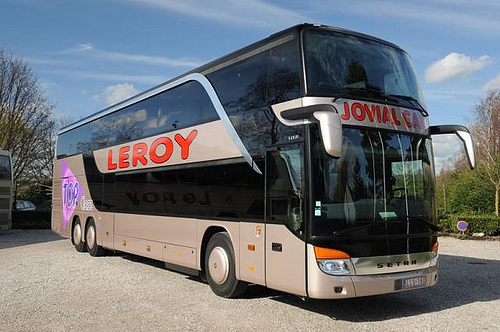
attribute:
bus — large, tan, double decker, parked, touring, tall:
[50, 22, 477, 303]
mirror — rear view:
[279, 102, 345, 161]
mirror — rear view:
[426, 123, 478, 170]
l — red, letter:
[106, 149, 118, 172]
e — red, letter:
[119, 145, 131, 168]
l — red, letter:
[390, 106, 402, 125]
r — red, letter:
[132, 142, 149, 167]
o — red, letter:
[148, 136, 174, 165]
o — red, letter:
[351, 101, 367, 121]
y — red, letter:
[174, 129, 199, 160]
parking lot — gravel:
[2, 227, 500, 330]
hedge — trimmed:
[439, 214, 499, 238]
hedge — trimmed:
[10, 208, 52, 228]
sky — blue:
[2, 1, 497, 179]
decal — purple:
[58, 159, 84, 236]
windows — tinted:
[54, 25, 437, 257]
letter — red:
[339, 101, 351, 123]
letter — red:
[363, 103, 377, 123]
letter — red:
[401, 109, 411, 128]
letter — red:
[375, 104, 384, 124]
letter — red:
[382, 104, 393, 124]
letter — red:
[410, 111, 420, 130]